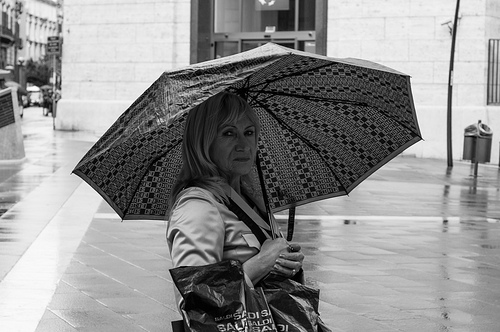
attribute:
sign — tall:
[48, 34, 62, 119]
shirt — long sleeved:
[164, 178, 287, 306]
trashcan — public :
[459, 117, 494, 172]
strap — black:
[178, 185, 267, 245]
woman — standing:
[160, 92, 332, 324]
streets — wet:
[0, 117, 494, 328]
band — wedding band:
[292, 267, 297, 274]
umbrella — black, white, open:
[69, 37, 429, 224]